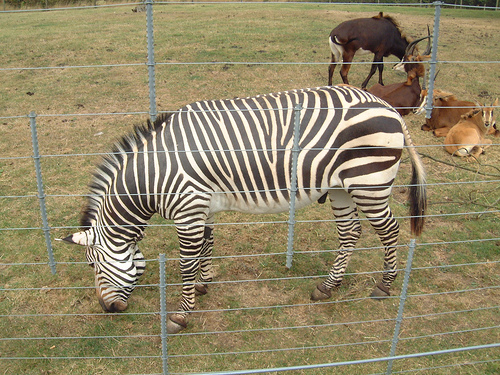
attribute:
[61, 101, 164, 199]
mane — black and white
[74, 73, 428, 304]
zebra — striped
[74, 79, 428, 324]
zebra — striped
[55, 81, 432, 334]
zebra — striped, black, white, bent down, big, grazing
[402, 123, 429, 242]
tail — white, black, zebra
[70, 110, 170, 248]
mane — black, white, zebra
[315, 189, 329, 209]
penis — zebra, black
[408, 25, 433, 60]
horns — black, animal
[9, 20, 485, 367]
fence — silver, metal, wire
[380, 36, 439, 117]
beast — brown, laying, hilde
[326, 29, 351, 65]
butt — hildebeast, white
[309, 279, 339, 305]
hoof — back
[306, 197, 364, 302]
leg — back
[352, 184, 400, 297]
leg — back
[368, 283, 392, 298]
hoof — back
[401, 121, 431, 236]
tail — white, black, zebra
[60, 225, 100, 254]
ear — zebra, beautiful, black, white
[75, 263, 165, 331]
grass — green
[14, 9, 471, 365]
fencing — silver, stainless, steel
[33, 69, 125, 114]
grass — green , dead 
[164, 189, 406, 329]
legs — four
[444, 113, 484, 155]
animal — brown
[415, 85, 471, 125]
animal — brown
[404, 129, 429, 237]
tail — black, white, zebra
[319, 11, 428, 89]
animal — brown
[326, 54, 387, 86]
legs — four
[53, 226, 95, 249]
ear — pointy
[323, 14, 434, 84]
animal — brown, horned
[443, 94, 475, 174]
animal — young, tan, looking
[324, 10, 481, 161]
animals — sitting, eating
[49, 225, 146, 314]
head — zebra, black, white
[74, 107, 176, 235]
mane — white, black, zebra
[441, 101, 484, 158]
animal — light brown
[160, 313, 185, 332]
hoof — zebra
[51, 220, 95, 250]
ear — zebra